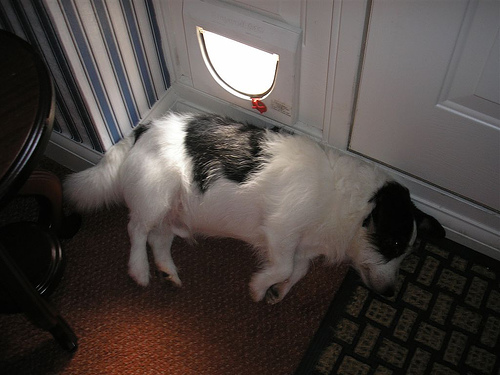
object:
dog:
[60, 107, 447, 305]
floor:
[0, 155, 500, 375]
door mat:
[293, 236, 500, 375]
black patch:
[180, 113, 267, 195]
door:
[345, 0, 500, 215]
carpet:
[0, 154, 349, 375]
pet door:
[181, 0, 305, 127]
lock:
[250, 95, 268, 113]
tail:
[62, 118, 154, 215]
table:
[0, 26, 83, 354]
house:
[0, 0, 500, 375]